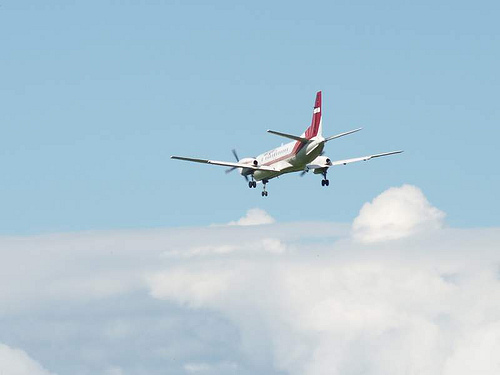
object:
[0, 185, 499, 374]
clouds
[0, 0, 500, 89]
sky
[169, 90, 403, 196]
airplane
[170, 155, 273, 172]
wing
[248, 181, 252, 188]
wheel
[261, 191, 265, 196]
wheel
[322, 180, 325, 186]
wheel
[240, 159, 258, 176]
engine